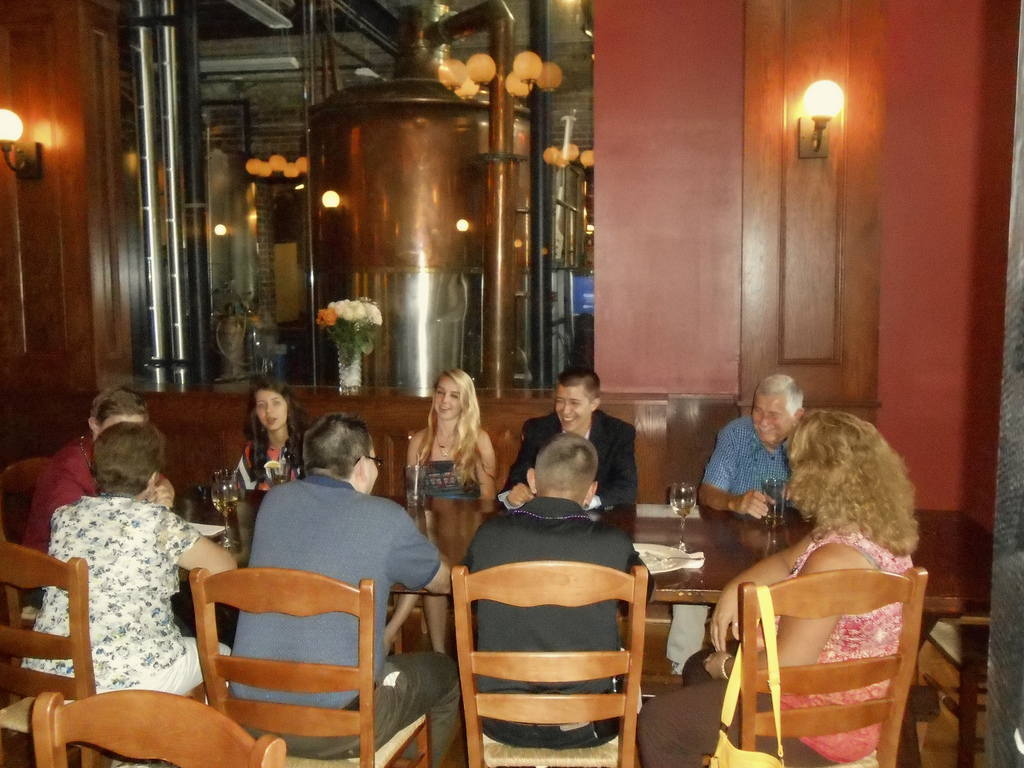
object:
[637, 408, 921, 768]
family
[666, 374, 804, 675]
family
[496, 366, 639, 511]
family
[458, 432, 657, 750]
family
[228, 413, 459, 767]
family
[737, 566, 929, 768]
chair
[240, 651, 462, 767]
pants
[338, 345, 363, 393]
vase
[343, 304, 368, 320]
flower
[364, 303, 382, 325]
flower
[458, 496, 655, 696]
jacket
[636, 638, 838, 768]
pants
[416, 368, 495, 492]
hair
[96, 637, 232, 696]
pants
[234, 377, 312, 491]
woman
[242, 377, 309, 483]
hair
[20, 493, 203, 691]
shirt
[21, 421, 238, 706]
woman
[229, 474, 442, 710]
shirt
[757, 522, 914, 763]
top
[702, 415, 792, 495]
shirt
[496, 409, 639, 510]
jacket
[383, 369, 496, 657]
girl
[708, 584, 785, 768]
bag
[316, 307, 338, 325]
flower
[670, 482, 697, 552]
glass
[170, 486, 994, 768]
table